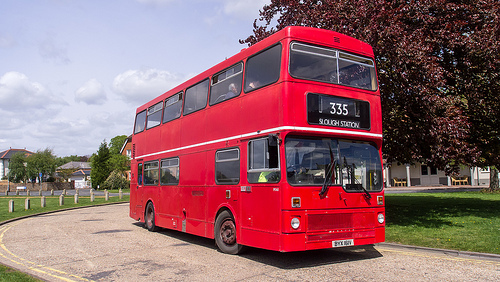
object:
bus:
[130, 26, 385, 255]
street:
[0, 216, 499, 282]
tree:
[239, 0, 499, 172]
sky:
[0, 0, 281, 157]